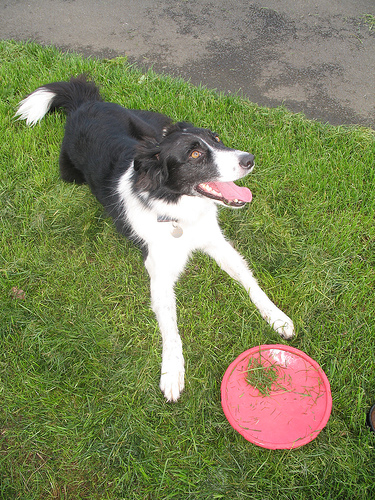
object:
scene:
[4, 7, 369, 499]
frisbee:
[219, 342, 333, 451]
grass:
[249, 362, 276, 396]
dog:
[9, 69, 296, 406]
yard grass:
[268, 122, 364, 198]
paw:
[274, 314, 297, 342]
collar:
[131, 190, 190, 221]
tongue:
[204, 181, 252, 204]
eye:
[213, 134, 221, 143]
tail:
[9, 65, 103, 129]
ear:
[128, 150, 167, 198]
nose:
[241, 154, 254, 169]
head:
[129, 118, 256, 211]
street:
[2, 0, 373, 123]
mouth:
[194, 166, 254, 212]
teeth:
[233, 198, 241, 205]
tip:
[11, 84, 53, 129]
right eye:
[187, 148, 204, 160]